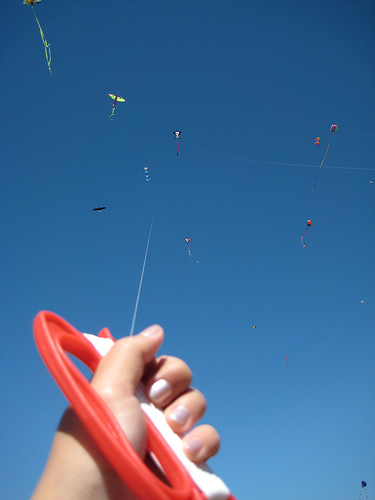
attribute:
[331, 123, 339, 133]
kite — multi colored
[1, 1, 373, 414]
sky — blue, bright, high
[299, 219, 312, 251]
kite — rainbow colored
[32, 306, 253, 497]
holder — red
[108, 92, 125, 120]
kite — yellow, green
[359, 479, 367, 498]
kite — purple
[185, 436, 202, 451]
polish — clear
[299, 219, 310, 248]
kite — red, high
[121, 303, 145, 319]
string — white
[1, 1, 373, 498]
sky — blue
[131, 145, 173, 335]
string — white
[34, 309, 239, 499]
handle — red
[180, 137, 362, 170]
thread — white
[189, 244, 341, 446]
thread — white